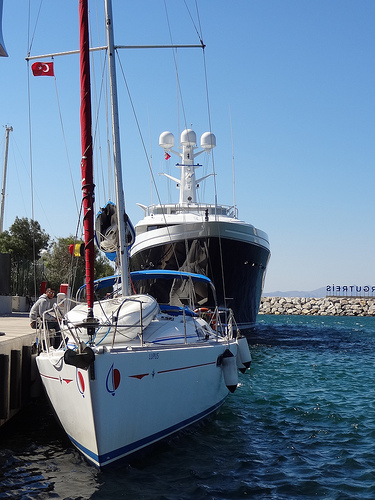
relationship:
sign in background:
[314, 265, 371, 308] [268, 234, 372, 354]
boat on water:
[77, 339, 225, 477] [214, 387, 373, 475]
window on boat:
[149, 202, 192, 217] [141, 231, 221, 279]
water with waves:
[214, 387, 373, 475] [188, 433, 281, 483]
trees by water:
[7, 210, 77, 264] [214, 387, 373, 475]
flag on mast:
[21, 42, 75, 97] [40, 97, 146, 220]